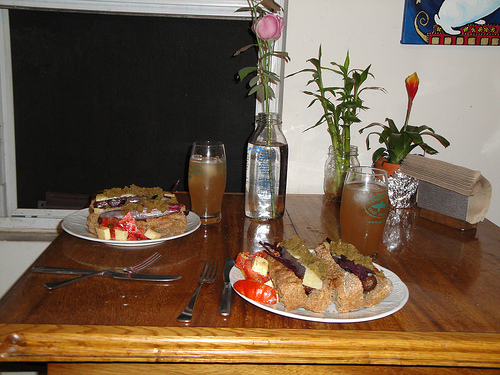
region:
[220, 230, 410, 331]
plate with dinner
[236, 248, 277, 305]
tomatoes on a plate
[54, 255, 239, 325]
silverware on a table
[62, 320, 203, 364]
wooden border of a table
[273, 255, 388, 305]
two hot dogs on a plate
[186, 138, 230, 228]
glass with ice in it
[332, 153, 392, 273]
glass of beer on a table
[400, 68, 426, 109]
red and yellow flower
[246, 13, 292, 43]
pink petals of a flower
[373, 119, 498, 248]
brown napkins in a holder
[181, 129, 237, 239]
This is a glass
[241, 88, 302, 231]
This is a glass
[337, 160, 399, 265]
This is a glass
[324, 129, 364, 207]
This is a glass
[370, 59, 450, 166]
This is a flower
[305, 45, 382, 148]
This is a flower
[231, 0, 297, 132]
This is a flower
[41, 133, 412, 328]
this is a meal set for two people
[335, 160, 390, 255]
the beverage of the evening looks like iced tea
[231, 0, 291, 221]
there is a lovely rose to decorate the table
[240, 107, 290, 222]
the "vase" for the rose is actualy a drink bottle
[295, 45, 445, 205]
there are other plants on the table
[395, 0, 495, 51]
there is a picture on the wall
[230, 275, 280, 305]
this looks like some kind of shellfish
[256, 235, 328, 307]
this looks like a crawfish on toast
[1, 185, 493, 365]
the meal is served on a wooden table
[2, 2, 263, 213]
the window is open and the screen is closed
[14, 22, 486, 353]
a meal on a table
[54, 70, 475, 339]
a meal made for two people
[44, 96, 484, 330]
these people are eating at home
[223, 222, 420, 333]
this is some kind of sausage based meal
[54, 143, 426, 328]
this is dinner for two people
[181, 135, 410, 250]
two drinks on the table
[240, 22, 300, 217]
a flower on the table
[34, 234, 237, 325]
silverwear on the table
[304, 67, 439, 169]
plants on the table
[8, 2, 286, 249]
a TV in the background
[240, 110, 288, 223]
a clear glass bottle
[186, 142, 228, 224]
a glass of iced tea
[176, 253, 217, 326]
a fork next to a knife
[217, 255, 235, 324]
a knife next to a plate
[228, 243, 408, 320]
a round white plate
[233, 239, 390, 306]
food filling a plate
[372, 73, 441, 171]
a potted flower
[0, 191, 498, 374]
a brown wood table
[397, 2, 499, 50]
a poster on a wall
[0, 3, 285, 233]
a window beside a table